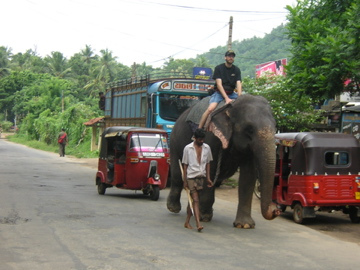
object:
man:
[191, 50, 244, 141]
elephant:
[164, 94, 282, 235]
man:
[177, 130, 216, 233]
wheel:
[140, 184, 163, 202]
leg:
[233, 164, 257, 230]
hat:
[221, 49, 240, 57]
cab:
[253, 128, 359, 224]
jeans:
[209, 89, 239, 106]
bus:
[103, 68, 219, 141]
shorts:
[184, 172, 209, 194]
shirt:
[212, 62, 244, 94]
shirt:
[180, 142, 215, 180]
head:
[220, 49, 238, 65]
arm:
[222, 96, 236, 106]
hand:
[206, 179, 216, 188]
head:
[208, 91, 282, 221]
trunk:
[251, 134, 284, 220]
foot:
[226, 212, 260, 231]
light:
[308, 180, 323, 191]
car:
[93, 123, 171, 202]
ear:
[202, 104, 234, 150]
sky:
[0, 0, 333, 70]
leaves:
[302, 34, 345, 77]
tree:
[277, 0, 359, 131]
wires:
[134, 0, 292, 15]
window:
[322, 150, 353, 169]